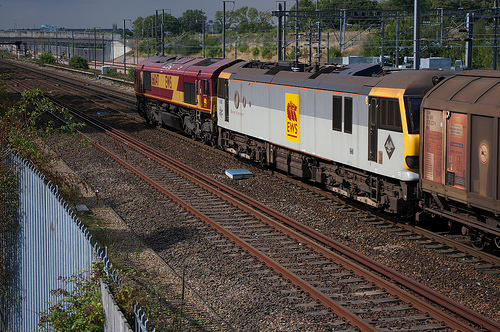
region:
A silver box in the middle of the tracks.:
[207, 151, 262, 181]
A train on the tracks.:
[138, 50, 494, 259]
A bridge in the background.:
[15, 11, 144, 51]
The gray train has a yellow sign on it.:
[247, 66, 314, 147]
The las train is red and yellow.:
[125, 53, 239, 129]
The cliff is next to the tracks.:
[10, 156, 93, 328]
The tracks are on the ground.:
[114, 142, 364, 324]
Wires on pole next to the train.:
[266, 8, 460, 79]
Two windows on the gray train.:
[321, 92, 377, 138]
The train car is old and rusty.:
[418, 89, 498, 249]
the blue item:
[212, 150, 276, 195]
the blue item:
[220, 148, 251, 188]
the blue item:
[223, 134, 273, 231]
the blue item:
[206, 160, 313, 234]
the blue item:
[227, 162, 264, 194]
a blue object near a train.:
[216, 160, 266, 184]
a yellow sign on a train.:
[274, 93, 309, 154]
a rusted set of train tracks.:
[0, 57, 488, 327]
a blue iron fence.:
[0, 147, 157, 328]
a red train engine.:
[130, 48, 233, 138]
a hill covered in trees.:
[125, 1, 497, 71]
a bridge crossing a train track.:
[0, 17, 141, 51]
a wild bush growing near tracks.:
[62, 55, 104, 63]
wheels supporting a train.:
[211, 123, 418, 226]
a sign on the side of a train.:
[377, 127, 400, 157]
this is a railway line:
[155, 160, 232, 220]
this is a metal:
[241, 238, 262, 270]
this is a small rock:
[221, 275, 248, 315]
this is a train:
[246, 70, 383, 154]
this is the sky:
[39, 2, 116, 22]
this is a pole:
[405, 12, 425, 59]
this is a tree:
[183, 5, 201, 34]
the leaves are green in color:
[181, 10, 203, 17]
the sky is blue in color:
[116, 7, 125, 12]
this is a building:
[12, 27, 103, 49]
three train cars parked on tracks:
[24, 14, 478, 324]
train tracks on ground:
[207, 148, 307, 309]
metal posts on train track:
[188, 161, 263, 273]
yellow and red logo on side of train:
[272, 91, 294, 138]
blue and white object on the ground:
[195, 151, 256, 199]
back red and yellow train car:
[105, 41, 246, 149]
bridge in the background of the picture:
[0, 11, 155, 65]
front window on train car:
[330, 94, 420, 155]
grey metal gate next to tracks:
[22, 160, 107, 330]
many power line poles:
[222, 10, 329, 61]